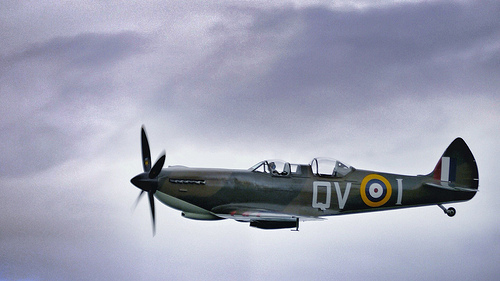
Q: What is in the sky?
A: A plane.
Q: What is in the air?
A: An airplane.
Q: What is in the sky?
A: Clouds.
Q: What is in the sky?
A: Clouds.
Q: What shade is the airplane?
A: Dark green.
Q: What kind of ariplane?
A: Old.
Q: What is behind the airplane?
A: Gray skies.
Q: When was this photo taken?
A: Day time.